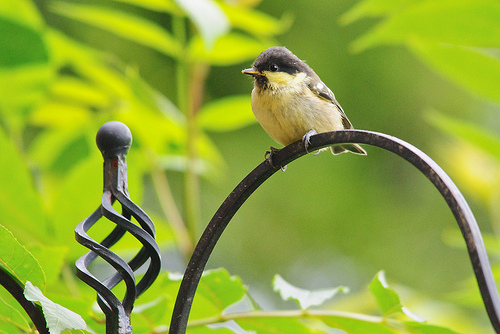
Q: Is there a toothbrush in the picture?
A: No, there are no toothbrushes.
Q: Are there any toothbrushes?
A: No, there are no toothbrushes.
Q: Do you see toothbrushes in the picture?
A: No, there are no toothbrushes.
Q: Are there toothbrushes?
A: No, there are no toothbrushes.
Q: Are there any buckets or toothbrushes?
A: No, there are no toothbrushes or buckets.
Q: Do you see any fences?
A: No, there are no fences.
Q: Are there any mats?
A: No, there are no mats.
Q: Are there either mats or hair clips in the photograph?
A: No, there are no mats or hair clips.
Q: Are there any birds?
A: Yes, there is a bird.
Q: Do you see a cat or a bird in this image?
A: Yes, there is a bird.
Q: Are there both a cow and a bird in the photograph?
A: No, there is a bird but no cows.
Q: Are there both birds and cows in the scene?
A: No, there is a bird but no cows.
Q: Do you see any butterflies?
A: No, there are no butterflies.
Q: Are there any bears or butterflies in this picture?
A: No, there are no butterflies or bears.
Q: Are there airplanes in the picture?
A: No, there are no airplanes.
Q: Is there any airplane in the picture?
A: No, there are no airplanes.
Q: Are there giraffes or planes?
A: No, there are no planes or giraffes.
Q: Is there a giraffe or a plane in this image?
A: No, there are no airplanes or giraffes.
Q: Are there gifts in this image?
A: No, there are no gifts.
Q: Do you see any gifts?
A: No, there are no gifts.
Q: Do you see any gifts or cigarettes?
A: No, there are no gifts or cigarettes.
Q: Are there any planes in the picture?
A: No, there are no planes.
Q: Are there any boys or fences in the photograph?
A: No, there are no fences or boys.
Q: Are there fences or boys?
A: No, there are no fences or boys.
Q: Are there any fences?
A: No, there are no fences.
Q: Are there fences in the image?
A: No, there are no fences.